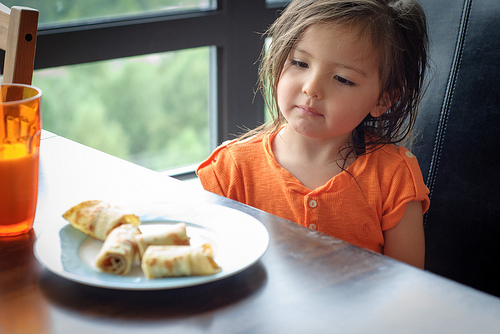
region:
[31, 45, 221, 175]
blurred landscape seen through window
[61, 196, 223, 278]
group of four eggrolls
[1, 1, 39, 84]
partial back of a chair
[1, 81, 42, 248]
orange colored drinking glass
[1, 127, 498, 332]
table reflecting light from the window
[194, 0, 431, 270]
young girl with solemn face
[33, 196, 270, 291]
plate of food on the table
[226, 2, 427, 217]
shoulder length stringy brown hair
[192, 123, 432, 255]
short sleeved orange cotton shirt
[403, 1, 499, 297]
black leather seat back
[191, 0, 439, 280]
Young girl eating food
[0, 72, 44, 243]
A glass of milk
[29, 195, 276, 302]
Plate with food on it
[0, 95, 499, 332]
Dinner table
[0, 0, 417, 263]
Window showing trees behind it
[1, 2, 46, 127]
Another chair at the table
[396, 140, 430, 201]
A button to shorten the girl's shirt sleeves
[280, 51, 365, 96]
Eyes looking at the plate of food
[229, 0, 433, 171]
The girl's hair, shoulder-length and combed to one side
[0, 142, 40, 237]
The portion of milk remaining in the glass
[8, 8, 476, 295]
the girl is sitting at the table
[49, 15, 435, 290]
she is looking at the food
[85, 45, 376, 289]
this girl is trying to decide if she wants to eat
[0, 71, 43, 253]
this is a cup of milk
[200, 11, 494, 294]
she is sitting in a booth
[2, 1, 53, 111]
this is a chair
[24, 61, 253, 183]
this is a window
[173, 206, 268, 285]
he plate is white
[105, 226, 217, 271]
these are eggrolls for eating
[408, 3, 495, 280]
the booth is black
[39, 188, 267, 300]
rolled sandwiches on a white plate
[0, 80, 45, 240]
amber glass half filled with milk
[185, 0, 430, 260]
girl wearing orange short sleeve shirt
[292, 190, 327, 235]
white buttons on an orange shirt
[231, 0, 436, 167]
little girl's head with brown hair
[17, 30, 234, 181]
green trees seen through a window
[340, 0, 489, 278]
back section of black chair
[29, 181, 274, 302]
white plate on a dark brown table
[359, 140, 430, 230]
short sleeve with button on a strap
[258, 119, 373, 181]
neck area of young girl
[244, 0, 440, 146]
A girl looking at something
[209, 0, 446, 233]
A girl with brown hair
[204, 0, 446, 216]
A girl wearing an orange shirt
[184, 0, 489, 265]
A girl sitting at a table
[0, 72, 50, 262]
A glass of milk on a table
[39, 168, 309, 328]
A white plate on the table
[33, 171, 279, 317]
A plate of food on the table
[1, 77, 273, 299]
A drink and food on the table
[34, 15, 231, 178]
A window by a table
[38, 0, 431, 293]
A girl looking at her food